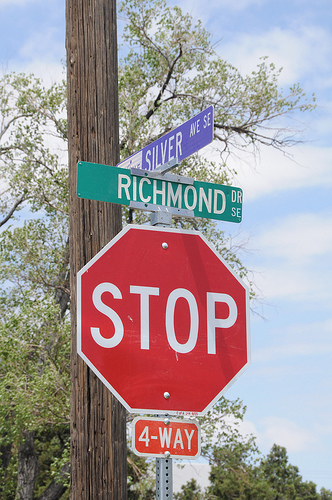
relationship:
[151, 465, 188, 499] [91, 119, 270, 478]
post has signs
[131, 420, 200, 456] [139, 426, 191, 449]
sign has 4 way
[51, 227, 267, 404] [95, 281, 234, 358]
sign reads stop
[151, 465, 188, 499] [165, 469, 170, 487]
post has holes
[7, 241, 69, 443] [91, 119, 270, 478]
trees behind signs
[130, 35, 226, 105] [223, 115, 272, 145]
tree has branch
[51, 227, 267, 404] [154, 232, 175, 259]
sign has bolt